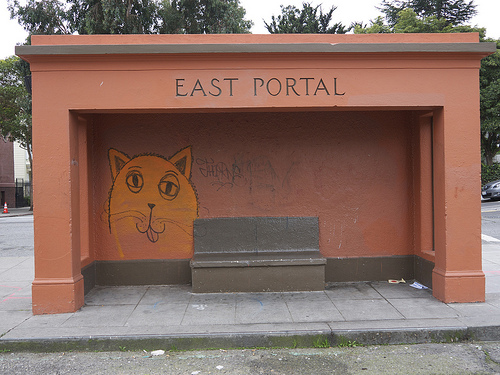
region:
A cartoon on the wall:
[100, 127, 200, 250]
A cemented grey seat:
[187, 215, 333, 301]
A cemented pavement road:
[30, 313, 309, 344]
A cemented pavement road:
[337, 281, 411, 351]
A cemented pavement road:
[20, 349, 122, 373]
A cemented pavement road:
[155, 344, 243, 373]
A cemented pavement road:
[334, 351, 495, 373]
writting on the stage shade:
[163, 45, 356, 107]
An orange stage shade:
[15, 43, 495, 346]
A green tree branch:
[2, 57, 39, 149]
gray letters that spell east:
[143, 68, 243, 124]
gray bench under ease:
[152, 203, 332, 336]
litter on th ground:
[335, 274, 425, 323]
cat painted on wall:
[78, 142, 207, 275]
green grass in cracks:
[237, 319, 388, 374]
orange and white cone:
[0, 188, 14, 218]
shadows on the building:
[2, 156, 38, 218]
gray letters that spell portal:
[240, 73, 356, 122]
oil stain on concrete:
[202, 343, 372, 373]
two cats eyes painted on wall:
[91, 160, 188, 212]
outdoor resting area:
[3, 22, 499, 309]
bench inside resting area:
[186, 208, 342, 305]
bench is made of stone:
[171, 206, 346, 292]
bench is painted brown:
[181, 213, 346, 300]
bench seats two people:
[178, 203, 331, 296]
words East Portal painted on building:
[176, 68, 352, 102]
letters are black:
[175, 63, 350, 103]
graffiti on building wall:
[196, 148, 415, 215]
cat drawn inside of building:
[98, 128, 203, 263]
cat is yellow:
[96, 135, 205, 265]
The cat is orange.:
[106, 138, 194, 252]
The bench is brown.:
[189, 217, 326, 289]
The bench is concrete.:
[189, 216, 325, 288]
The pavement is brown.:
[96, 297, 175, 324]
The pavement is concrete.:
[108, 296, 190, 327]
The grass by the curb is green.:
[309, 334, 361, 351]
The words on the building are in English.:
[173, 71, 345, 103]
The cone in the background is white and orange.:
[1, 197, 7, 216]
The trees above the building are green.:
[88, 3, 167, 28]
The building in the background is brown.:
[0, 140, 12, 172]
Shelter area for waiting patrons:
[13, 30, 499, 302]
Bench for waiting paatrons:
[188, 208, 330, 295]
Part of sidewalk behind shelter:
[5, 229, 28, 281]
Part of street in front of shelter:
[206, 352, 340, 373]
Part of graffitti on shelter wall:
[93, 142, 208, 268]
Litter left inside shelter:
[386, 270, 427, 293]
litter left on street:
[146, 345, 173, 361]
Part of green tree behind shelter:
[71, 2, 146, 29]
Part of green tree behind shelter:
[13, 4, 63, 35]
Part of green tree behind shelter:
[397, 5, 455, 18]